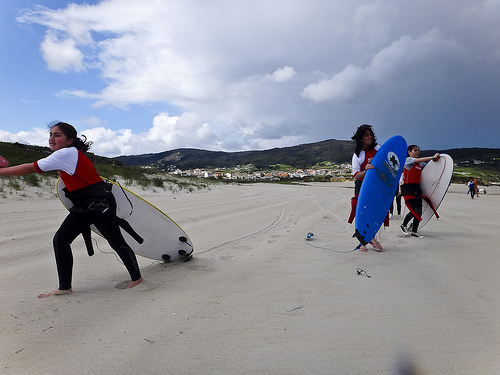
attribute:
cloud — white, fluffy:
[165, 8, 359, 91]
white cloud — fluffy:
[301, 62, 374, 106]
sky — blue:
[2, 1, 497, 151]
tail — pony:
[76, 135, 91, 152]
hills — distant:
[0, 131, 397, 183]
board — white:
[53, 172, 194, 262]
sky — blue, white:
[21, 4, 491, 119]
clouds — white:
[107, 7, 499, 143]